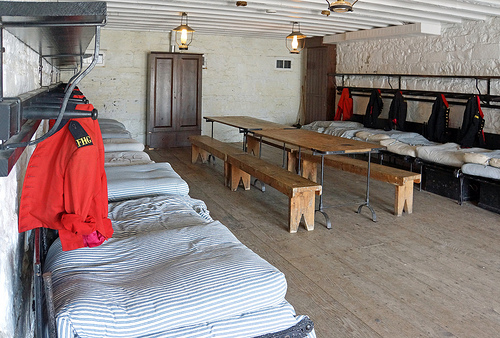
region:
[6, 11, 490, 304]
the inside of soldier's sleeping quarters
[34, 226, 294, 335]
a blue striped unmade bed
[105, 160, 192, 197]
a blue striped unmade bed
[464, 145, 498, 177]
a blue striped unmade bed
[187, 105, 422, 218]
two wooden tables and four benches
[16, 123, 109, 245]
a red soldier's jacket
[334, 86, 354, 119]
a red soldier's jacket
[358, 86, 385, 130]
a red and black soldier's jacket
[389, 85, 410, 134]
a red and black soldier's jacket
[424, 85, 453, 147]
a red and black soldier's jacket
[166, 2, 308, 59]
Two light fixtures hanging from the ceiling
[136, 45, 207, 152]
A tall brown wooden cabinet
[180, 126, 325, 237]
The benches are wooden and brown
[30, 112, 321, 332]
A row of beds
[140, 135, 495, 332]
The floor is made of wood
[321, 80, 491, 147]
A red coat hanging next to four black coats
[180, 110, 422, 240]
Benches on both sides of a table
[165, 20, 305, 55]
The lights are turned on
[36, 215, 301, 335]
A bed has white bed sheets on it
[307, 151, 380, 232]
Two metal legs of a table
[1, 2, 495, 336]
a large room that seems to serve as a dormitory and dining room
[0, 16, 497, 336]
white walls have a rough-looking surface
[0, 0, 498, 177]
small metal posts affixed to long bars on walls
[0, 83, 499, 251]
red and black jackets hung from metal posts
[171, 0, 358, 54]
lantern-style lights hung from ceiling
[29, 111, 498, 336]
mattresses on cots along walls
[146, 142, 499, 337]
floor is composed of unfinished wood boards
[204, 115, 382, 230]
two wood-topped tables with metal legs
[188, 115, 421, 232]
long wooden benches near tables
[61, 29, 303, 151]
vent is on the same wall as the door is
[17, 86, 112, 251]
red fireman's jacket hanging from hook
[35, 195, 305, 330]
folded bunk style mattress near shirt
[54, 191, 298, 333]
blue and white striped mattress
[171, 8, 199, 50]
old hanging kerosine style lamp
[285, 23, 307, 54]
old hanging kerosine style lamp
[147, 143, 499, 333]
plain hardwood floors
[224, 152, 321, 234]
simple hardwood bench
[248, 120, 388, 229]
long hardwood table with metal legs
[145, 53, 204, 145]
heavy wooden door with low brass door handles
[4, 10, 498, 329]
indoor display of early firemen working conditions